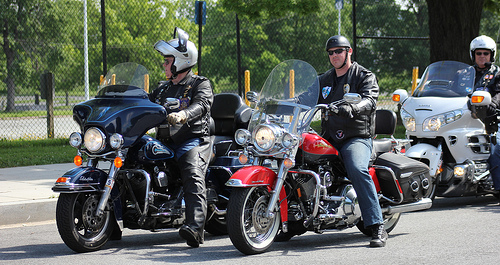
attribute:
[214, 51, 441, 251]
motorcycle — red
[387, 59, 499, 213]
motorcycle — white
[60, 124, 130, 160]
three lights — on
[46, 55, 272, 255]
motorcycle — black, blue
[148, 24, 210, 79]
helmet — gray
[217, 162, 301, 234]
fender — red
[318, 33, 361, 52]
helmet — black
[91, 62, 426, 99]
pillars — yellow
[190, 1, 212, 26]
sign — blue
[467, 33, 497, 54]
helmet — white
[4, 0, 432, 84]
trees — green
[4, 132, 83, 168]
grass — green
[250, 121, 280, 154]
front middle light — on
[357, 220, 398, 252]
shoes — black